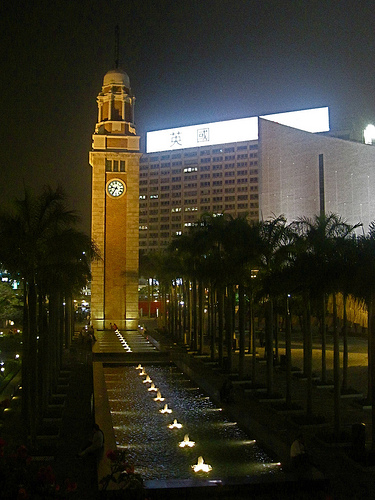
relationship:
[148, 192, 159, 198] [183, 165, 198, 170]
window with window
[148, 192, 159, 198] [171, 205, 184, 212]
window with window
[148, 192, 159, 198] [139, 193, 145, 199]
window with window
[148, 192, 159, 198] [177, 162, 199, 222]
window with lights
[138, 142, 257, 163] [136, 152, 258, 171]
window row on side of window row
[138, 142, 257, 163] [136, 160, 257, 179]
window row on side of window row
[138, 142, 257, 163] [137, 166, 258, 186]
window row on side of window row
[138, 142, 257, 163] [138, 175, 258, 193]
window row on side of window row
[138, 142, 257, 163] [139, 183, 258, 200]
window row on side of window row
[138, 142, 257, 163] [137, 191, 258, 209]
window row on side of window row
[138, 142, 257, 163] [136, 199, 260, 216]
window row on side of window row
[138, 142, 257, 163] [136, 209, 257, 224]
window row on side of window row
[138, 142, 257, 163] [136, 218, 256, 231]
window row on side of window row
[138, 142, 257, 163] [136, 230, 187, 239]
window row on side of window row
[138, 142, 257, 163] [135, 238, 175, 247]
window row on side of window row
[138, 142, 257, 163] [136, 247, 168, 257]
window row on side of window row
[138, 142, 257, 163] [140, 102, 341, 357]
window row on side of building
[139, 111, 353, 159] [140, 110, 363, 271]
billboard on top of building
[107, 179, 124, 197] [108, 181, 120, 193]
face with markings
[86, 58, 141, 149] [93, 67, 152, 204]
dome on clock tower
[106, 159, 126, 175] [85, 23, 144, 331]
windows on building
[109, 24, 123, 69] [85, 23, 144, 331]
pole on building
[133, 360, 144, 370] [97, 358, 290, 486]
light in pool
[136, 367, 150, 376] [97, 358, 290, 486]
light in pool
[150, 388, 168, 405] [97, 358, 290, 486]
light in pool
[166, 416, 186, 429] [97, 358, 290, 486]
light in pool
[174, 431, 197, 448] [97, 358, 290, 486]
light in pool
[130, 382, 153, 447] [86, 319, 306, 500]
water in pool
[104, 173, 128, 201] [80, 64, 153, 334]
clock on building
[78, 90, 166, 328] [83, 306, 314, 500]
building behind pool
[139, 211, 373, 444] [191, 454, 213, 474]
trees lining candle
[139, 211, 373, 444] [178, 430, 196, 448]
trees lining candle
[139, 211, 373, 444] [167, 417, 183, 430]
trees lining light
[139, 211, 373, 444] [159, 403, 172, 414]
trees lining candle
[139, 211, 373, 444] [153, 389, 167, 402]
trees lining light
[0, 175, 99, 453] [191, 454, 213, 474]
trees lining candle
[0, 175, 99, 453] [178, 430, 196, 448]
trees lining candle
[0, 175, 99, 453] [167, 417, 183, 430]
trees lining light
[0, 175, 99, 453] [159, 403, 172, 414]
trees lining candle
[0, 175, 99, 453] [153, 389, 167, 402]
trees lining light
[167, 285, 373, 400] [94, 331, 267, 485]
trunks next to pool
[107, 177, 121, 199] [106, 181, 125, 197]
face of clock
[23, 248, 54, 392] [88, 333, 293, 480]
tree to left of water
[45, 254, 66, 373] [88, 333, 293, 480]
tree to left of water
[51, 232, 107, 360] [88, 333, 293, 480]
tree to left of water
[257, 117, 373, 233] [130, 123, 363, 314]
wall on side of building